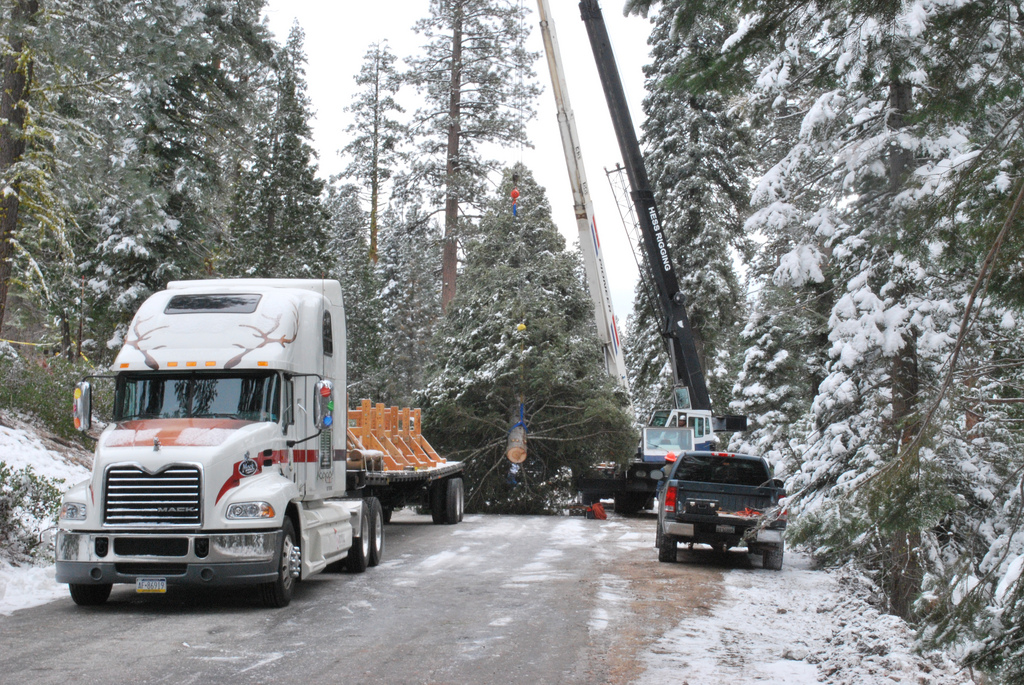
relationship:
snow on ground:
[193, 639, 295, 679] [15, 470, 985, 678]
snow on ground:
[411, 547, 460, 573] [15, 470, 985, 678]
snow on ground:
[550, 515, 649, 553] [15, 470, 985, 678]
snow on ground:
[3, 414, 93, 612] [15, 470, 985, 678]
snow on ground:
[636, 569, 973, 683] [15, 470, 985, 678]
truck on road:
[655, 449, 785, 567] [0, 483, 940, 680]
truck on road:
[54, 275, 467, 608] [0, 483, 940, 680]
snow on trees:
[250, 38, 438, 324] [15, 6, 1012, 607]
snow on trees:
[6, 4, 185, 356] [15, 6, 1012, 607]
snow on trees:
[421, 161, 612, 402] [15, 6, 1012, 607]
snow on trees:
[658, 0, 1020, 674] [15, 6, 1012, 607]